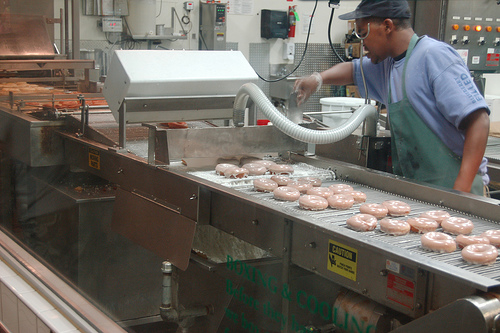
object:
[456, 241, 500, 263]
donuts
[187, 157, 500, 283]
tray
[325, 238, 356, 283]
warning sticker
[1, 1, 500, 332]
equipment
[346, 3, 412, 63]
head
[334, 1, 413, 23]
cap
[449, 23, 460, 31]
button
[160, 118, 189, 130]
donut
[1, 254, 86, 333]
tiles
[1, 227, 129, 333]
window sill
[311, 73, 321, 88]
watch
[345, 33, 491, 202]
shirt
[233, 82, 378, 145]
hose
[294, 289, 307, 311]
writing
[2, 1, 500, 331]
window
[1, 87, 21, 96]
donuts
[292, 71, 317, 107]
hand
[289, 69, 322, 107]
glove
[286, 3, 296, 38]
fire extinguisher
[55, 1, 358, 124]
wall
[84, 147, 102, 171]
warning sticker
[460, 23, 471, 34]
button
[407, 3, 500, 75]
box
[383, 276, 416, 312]
sign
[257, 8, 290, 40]
box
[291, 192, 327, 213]
donut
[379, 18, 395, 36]
ear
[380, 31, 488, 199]
apron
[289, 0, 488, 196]
man